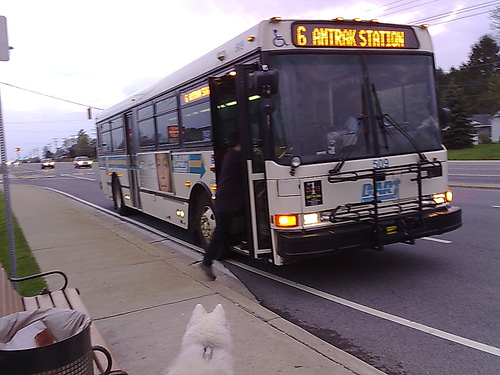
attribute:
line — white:
[338, 290, 437, 344]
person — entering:
[144, 36, 454, 265]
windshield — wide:
[267, 41, 453, 149]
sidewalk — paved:
[29, 197, 243, 352]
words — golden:
[270, 8, 417, 59]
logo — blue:
[341, 166, 428, 215]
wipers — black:
[295, 77, 455, 187]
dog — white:
[158, 289, 267, 369]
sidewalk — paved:
[61, 202, 226, 348]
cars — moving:
[13, 144, 96, 172]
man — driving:
[312, 84, 406, 152]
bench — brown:
[10, 259, 123, 366]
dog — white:
[175, 300, 253, 371]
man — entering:
[184, 140, 293, 270]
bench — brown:
[1, 265, 126, 372]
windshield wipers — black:
[370, 111, 424, 154]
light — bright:
[179, 82, 209, 102]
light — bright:
[310, 27, 359, 43]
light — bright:
[356, 31, 405, 45]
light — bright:
[274, 213, 297, 229]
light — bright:
[428, 191, 451, 203]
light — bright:
[170, 209, 184, 218]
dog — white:
[163, 298, 232, 372]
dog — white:
[169, 289, 235, 372]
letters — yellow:
[296, 24, 403, 46]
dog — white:
[159, 301, 237, 373]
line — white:
[291, 271, 498, 364]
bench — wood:
[0, 253, 126, 373]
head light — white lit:
[299, 210, 331, 229]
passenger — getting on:
[188, 126, 273, 276]